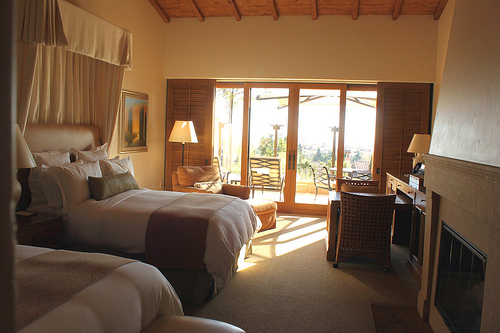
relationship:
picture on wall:
[117, 85, 151, 155] [17, 0, 166, 187]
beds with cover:
[0, 132, 298, 320] [110, 146, 237, 252]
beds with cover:
[0, 132, 298, 320] [7, 236, 188, 331]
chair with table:
[333, 190, 398, 270] [326, 186, 337, 266]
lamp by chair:
[167, 120, 198, 167] [172, 166, 278, 233]